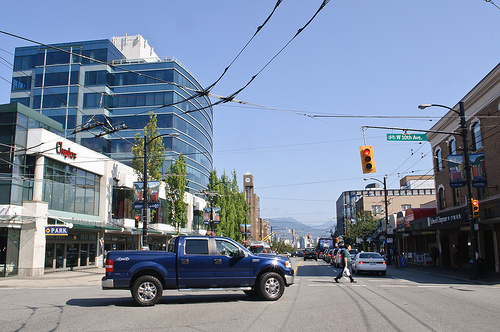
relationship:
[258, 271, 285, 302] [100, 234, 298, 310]
wheel underneath a truck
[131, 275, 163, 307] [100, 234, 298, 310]
wheel underneath a truck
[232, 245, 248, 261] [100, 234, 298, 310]
mirror front right of truck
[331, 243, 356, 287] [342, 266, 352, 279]
man carrying a grocery bag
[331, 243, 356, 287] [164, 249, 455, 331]
man walking across a street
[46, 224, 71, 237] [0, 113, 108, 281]
parking sign on side of a building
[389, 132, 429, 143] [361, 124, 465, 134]
street sign attached to a pole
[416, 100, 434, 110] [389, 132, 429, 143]
street light above street sign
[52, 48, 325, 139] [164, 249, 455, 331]
electric cables are dangling above a street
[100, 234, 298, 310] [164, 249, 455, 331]
truck on top of street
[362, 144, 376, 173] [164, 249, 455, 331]
stoplight above street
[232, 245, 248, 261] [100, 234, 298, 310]
mirror on front right of truck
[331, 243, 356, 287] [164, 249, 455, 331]
man crossing street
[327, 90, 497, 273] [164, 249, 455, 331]
buildings line side of street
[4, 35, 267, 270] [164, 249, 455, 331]
buildings line side of street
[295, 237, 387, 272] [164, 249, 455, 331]
vehicles are on top of street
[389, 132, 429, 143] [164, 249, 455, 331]
street sign above street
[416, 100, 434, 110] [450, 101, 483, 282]
street light left of a pole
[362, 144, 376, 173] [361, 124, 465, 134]
stoplight hangs below a pole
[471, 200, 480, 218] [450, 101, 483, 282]
street light hangs from a pole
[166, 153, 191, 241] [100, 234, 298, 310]
tree behind truck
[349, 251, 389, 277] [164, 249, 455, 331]
car on top of street